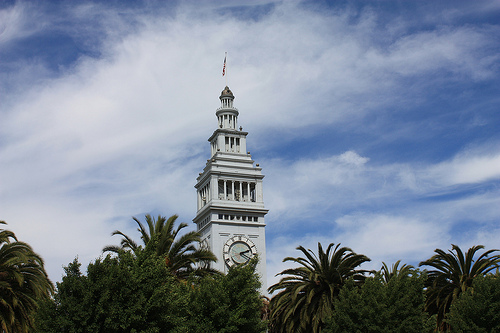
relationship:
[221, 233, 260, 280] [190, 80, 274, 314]
clock on side of building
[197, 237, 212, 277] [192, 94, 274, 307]
clock on side of building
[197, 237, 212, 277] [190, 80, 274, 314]
clock on side of building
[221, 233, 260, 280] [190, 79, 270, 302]
clock on side of building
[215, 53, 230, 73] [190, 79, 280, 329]
flag on top of building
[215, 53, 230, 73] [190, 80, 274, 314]
flag on top of building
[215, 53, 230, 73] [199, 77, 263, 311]
flag on top of building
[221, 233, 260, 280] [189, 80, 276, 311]
clock on tower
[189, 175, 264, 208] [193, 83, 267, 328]
bell portion on tower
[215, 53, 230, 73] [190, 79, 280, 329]
flag on building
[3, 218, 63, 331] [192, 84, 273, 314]
tree by steeple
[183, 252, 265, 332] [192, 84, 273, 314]
tree by steeple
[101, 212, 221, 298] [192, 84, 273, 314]
tree by steeple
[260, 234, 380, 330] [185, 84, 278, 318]
tree by steeple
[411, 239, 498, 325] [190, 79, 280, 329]
tree by building